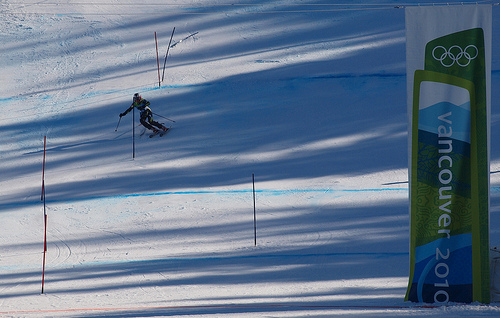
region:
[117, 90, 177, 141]
person on skiis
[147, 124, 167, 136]
two skiis on the person's feet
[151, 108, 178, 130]
skii rod in the person's left hand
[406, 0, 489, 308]
olympic banner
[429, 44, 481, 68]
olympic ring symbol on the banner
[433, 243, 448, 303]
the year 2010 on the banner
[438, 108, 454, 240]
"vancouver" on the banner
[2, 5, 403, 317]
skii slope used for professional skiing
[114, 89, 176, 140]
person is skiing down a slope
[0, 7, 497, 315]
fresh snow on the ground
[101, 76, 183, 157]
the man on skis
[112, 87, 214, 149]
the man is sking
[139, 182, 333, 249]
blue paint in the snow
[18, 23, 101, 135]
tracks in the snow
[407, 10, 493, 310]
the winter olympics flag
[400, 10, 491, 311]
the winter olympics flag is hanging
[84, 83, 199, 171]
the man holding ski poles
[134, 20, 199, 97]
poles in the snow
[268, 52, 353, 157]
snow on the slope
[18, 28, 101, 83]
the sun is shining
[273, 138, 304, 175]
part of a shhade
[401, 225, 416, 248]
edge of a banner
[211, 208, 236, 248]
part of a shade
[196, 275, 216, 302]
part of a snow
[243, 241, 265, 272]
part of a shade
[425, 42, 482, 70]
rings of the Olympic symbol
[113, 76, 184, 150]
skier going down the slope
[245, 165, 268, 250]
pole on the ski slope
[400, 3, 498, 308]
flag at the side of the ski slope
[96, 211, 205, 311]
snow on the ski slope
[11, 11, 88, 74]
tracks in the snow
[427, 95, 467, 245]
name of the place of the Olympics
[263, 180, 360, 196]
blue line in the snow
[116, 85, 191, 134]
skier wearing a helmet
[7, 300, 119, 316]
red line in the snow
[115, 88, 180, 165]
person snow skiing down hill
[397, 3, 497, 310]
outside flag sign in snow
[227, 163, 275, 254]
pole in snow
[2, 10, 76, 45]
snow with tracks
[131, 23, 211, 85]
three poles in snow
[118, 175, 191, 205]
blue marking in snow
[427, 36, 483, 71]
Olympic sign on flag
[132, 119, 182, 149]
two snow skis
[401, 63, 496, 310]
Vancouver 2010 flag sign in snow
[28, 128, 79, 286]
several poles in snow